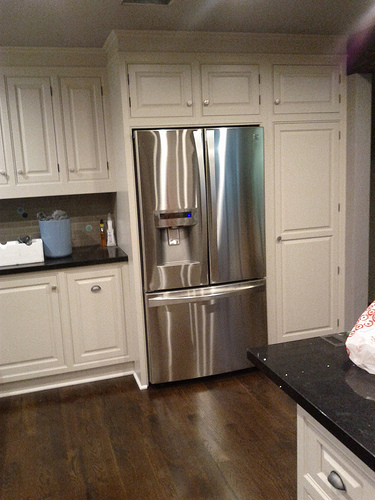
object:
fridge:
[127, 121, 278, 390]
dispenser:
[155, 210, 196, 269]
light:
[186, 212, 193, 220]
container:
[0, 236, 49, 270]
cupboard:
[123, 55, 198, 122]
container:
[37, 213, 74, 259]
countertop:
[245, 323, 374, 471]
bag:
[344, 296, 375, 373]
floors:
[2, 366, 295, 498]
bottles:
[104, 211, 117, 247]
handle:
[186, 98, 194, 110]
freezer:
[136, 279, 271, 387]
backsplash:
[0, 193, 128, 274]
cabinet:
[266, 117, 346, 343]